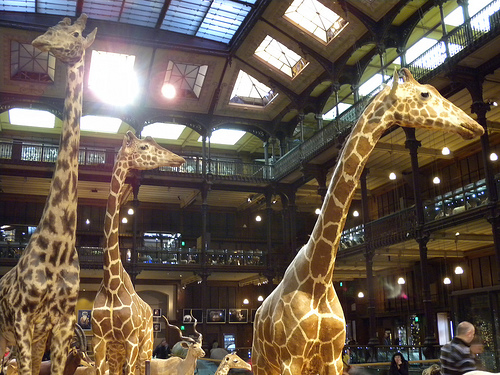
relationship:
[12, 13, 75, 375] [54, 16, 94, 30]
statue has horns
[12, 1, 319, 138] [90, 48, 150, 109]
ceiling has skylight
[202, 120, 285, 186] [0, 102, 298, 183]
arch on third floor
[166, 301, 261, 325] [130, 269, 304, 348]
pictures on wall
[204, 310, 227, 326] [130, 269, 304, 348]
pictures on wall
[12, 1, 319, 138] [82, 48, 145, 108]
ceiling has skylight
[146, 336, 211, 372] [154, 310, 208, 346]
deer has antlers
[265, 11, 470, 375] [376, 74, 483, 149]
giraffe has head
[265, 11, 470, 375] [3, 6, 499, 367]
giraffe in building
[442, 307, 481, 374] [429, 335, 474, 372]
man wearing shirt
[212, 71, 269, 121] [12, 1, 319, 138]
window on ceiling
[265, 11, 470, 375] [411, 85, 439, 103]
giraffe has eye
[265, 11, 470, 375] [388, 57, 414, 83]
giraffe has ear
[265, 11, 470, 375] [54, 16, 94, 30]
giraffe has horns